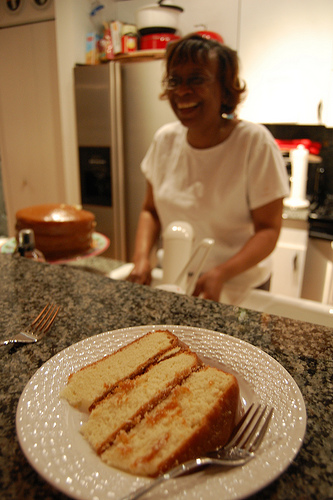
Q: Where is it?
A: This is at the kitchen.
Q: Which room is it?
A: It is a kitchen.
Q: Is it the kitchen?
A: Yes, it is the kitchen.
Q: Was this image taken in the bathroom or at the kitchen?
A: It was taken at the kitchen.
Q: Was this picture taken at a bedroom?
A: No, the picture was taken in a kitchen.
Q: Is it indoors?
A: Yes, it is indoors.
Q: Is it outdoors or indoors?
A: It is indoors.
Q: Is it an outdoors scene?
A: No, it is indoors.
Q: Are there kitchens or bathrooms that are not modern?
A: No, there is a kitchen but it is modern.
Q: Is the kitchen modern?
A: Yes, the kitchen is modern.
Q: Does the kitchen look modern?
A: Yes, the kitchen is modern.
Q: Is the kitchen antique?
A: No, the kitchen is modern.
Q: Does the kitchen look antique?
A: No, the kitchen is modern.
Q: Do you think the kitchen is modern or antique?
A: The kitchen is modern.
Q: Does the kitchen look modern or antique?
A: The kitchen is modern.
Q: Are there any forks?
A: Yes, there is a fork.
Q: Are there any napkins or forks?
A: Yes, there is a fork.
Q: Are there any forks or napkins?
A: Yes, there is a fork.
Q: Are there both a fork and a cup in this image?
A: No, there is a fork but no cups.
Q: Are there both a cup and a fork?
A: No, there is a fork but no cups.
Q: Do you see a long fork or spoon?
A: Yes, there is a long fork.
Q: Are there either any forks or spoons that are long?
A: Yes, the fork is long.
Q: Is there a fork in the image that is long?
A: Yes, there is a long fork.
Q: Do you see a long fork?
A: Yes, there is a long fork.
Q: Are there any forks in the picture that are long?
A: Yes, there is a fork that is long.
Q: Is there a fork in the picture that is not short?
A: Yes, there is a long fork.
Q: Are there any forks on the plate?
A: Yes, there is a fork on the plate.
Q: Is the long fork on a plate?
A: Yes, the fork is on a plate.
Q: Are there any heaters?
A: No, there are no heaters.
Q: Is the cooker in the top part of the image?
A: Yes, the cooker is in the top of the image.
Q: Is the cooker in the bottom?
A: No, the cooker is in the top of the image.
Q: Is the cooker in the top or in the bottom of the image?
A: The cooker is in the top of the image.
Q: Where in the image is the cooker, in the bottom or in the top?
A: The cooker is in the top of the image.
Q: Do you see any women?
A: Yes, there is a woman.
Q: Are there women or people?
A: Yes, there is a woman.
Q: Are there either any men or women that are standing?
A: Yes, the woman is standing.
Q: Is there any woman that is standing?
A: Yes, there is a woman that is standing.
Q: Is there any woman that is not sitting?
A: Yes, there is a woman that is standing.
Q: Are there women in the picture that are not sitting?
A: Yes, there is a woman that is standing.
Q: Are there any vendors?
A: No, there are no vendors.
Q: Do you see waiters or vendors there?
A: No, there are no vendors or waiters.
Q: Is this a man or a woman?
A: This is a woman.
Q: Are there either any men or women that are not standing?
A: No, there is a woman but she is standing.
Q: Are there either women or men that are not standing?
A: No, there is a woman but she is standing.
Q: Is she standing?
A: Yes, the woman is standing.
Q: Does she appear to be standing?
A: Yes, the woman is standing.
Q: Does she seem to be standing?
A: Yes, the woman is standing.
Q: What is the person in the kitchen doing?
A: The woman is standing.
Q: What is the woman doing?
A: The woman is standing.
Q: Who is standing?
A: The woman is standing.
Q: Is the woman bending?
A: No, the woman is standing.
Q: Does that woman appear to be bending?
A: No, the woman is standing.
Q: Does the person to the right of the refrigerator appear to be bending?
A: No, the woman is standing.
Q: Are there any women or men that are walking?
A: No, there is a woman but she is standing.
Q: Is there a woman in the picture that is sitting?
A: No, there is a woman but she is standing.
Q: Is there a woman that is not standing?
A: No, there is a woman but she is standing.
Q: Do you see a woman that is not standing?
A: No, there is a woman but she is standing.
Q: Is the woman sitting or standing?
A: The woman is standing.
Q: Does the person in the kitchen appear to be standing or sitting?
A: The woman is standing.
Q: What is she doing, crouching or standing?
A: The woman is standing.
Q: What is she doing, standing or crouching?
A: The woman is standing.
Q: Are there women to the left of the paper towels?
A: Yes, there is a woman to the left of the paper towels.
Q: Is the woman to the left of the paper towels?
A: Yes, the woman is to the left of the paper towels.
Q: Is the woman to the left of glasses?
A: No, the woman is to the left of the paper towels.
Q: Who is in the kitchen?
A: The woman is in the kitchen.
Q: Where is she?
A: The woman is in the kitchen.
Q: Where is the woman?
A: The woman is in the kitchen.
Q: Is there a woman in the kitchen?
A: Yes, there is a woman in the kitchen.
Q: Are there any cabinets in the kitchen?
A: No, there is a woman in the kitchen.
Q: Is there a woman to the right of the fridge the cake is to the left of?
A: Yes, there is a woman to the right of the refrigerator.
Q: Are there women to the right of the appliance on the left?
A: Yes, there is a woman to the right of the refrigerator.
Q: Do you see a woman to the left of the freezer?
A: No, the woman is to the right of the freezer.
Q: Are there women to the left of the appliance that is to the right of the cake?
A: No, the woman is to the right of the freezer.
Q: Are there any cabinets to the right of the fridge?
A: No, there is a woman to the right of the fridge.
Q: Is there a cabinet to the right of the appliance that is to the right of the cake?
A: No, there is a woman to the right of the fridge.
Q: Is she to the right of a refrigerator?
A: Yes, the woman is to the right of a refrigerator.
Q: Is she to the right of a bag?
A: No, the woman is to the right of a refrigerator.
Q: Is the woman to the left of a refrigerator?
A: No, the woman is to the right of a refrigerator.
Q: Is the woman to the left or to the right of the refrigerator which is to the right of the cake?
A: The woman is to the right of the freezer.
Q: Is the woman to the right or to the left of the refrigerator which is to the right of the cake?
A: The woman is to the right of the freezer.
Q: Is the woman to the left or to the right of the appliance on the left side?
A: The woman is to the right of the freezer.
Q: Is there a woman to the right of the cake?
A: Yes, there is a woman to the right of the cake.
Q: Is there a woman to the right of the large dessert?
A: Yes, there is a woman to the right of the cake.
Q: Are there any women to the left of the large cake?
A: No, the woman is to the right of the cake.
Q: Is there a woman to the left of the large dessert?
A: No, the woman is to the right of the cake.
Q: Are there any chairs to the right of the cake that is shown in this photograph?
A: No, there is a woman to the right of the cake.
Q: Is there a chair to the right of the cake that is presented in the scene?
A: No, there is a woman to the right of the cake.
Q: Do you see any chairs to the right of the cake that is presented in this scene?
A: No, there is a woman to the right of the cake.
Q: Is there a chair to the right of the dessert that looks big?
A: No, there is a woman to the right of the cake.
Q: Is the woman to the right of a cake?
A: Yes, the woman is to the right of a cake.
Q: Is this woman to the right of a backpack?
A: No, the woman is to the right of a cake.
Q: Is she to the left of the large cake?
A: No, the woman is to the right of the cake.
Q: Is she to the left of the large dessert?
A: No, the woman is to the right of the cake.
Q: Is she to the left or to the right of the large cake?
A: The woman is to the right of the cake.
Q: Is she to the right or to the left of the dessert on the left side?
A: The woman is to the right of the cake.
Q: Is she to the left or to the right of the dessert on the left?
A: The woman is to the right of the cake.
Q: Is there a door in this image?
A: Yes, there is a door.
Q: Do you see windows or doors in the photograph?
A: Yes, there is a door.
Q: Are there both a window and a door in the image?
A: No, there is a door but no windows.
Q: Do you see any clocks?
A: No, there are no clocks.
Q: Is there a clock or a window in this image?
A: No, there are no clocks or windows.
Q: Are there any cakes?
A: Yes, there is a cake.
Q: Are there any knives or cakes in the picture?
A: Yes, there is a cake.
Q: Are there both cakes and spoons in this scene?
A: No, there is a cake but no spoons.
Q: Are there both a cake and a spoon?
A: No, there is a cake but no spoons.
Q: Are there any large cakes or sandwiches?
A: Yes, there is a large cake.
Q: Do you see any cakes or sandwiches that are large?
A: Yes, the cake is large.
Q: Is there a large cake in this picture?
A: Yes, there is a large cake.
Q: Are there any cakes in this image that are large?
A: Yes, there is a cake that is large.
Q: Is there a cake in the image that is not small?
A: Yes, there is a large cake.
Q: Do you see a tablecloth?
A: No, there are no tablecloths.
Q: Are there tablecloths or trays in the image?
A: No, there are no tablecloths or trays.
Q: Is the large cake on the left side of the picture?
A: Yes, the cake is on the left of the image.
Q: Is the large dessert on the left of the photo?
A: Yes, the cake is on the left of the image.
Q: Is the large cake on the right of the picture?
A: No, the cake is on the left of the image.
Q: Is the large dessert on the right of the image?
A: No, the cake is on the left of the image.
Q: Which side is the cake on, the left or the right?
A: The cake is on the left of the image.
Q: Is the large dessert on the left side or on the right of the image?
A: The cake is on the left of the image.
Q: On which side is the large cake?
A: The cake is on the left of the image.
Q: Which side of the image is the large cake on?
A: The cake is on the left of the image.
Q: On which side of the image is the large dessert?
A: The cake is on the left of the image.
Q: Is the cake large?
A: Yes, the cake is large.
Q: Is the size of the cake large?
A: Yes, the cake is large.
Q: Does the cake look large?
A: Yes, the cake is large.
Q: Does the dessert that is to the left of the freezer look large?
A: Yes, the cake is large.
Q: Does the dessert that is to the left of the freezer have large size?
A: Yes, the cake is large.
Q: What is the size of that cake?
A: The cake is large.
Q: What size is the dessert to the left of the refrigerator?
A: The cake is large.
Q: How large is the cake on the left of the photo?
A: The cake is large.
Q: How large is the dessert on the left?
A: The cake is large.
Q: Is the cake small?
A: No, the cake is large.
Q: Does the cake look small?
A: No, the cake is large.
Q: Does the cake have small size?
A: No, the cake is large.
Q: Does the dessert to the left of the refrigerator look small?
A: No, the cake is large.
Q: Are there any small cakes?
A: No, there is a cake but it is large.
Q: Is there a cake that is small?
A: No, there is a cake but it is large.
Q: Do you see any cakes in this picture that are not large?
A: No, there is a cake but it is large.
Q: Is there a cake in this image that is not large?
A: No, there is a cake but it is large.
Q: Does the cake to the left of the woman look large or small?
A: The cake is large.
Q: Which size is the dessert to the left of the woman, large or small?
A: The cake is large.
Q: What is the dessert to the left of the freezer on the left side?
A: The dessert is a cake.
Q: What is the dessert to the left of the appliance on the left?
A: The dessert is a cake.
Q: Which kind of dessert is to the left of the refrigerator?
A: The dessert is a cake.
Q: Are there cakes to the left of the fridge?
A: Yes, there is a cake to the left of the fridge.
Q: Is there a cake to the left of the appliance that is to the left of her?
A: Yes, there is a cake to the left of the fridge.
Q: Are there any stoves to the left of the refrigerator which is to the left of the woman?
A: No, there is a cake to the left of the refrigerator.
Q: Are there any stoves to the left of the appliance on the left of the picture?
A: No, there is a cake to the left of the refrigerator.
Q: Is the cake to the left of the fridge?
A: Yes, the cake is to the left of the fridge.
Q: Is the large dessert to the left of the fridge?
A: Yes, the cake is to the left of the fridge.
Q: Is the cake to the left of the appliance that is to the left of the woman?
A: Yes, the cake is to the left of the fridge.